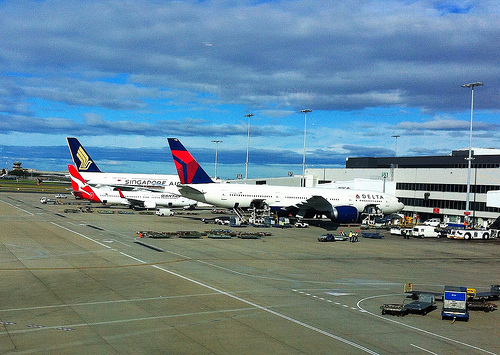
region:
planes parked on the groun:
[45, 112, 437, 265]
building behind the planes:
[291, 114, 496, 214]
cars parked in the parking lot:
[393, 208, 486, 296]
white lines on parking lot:
[118, 224, 271, 346]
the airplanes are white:
[219, 159, 403, 229]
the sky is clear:
[116, 92, 241, 131]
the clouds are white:
[88, 89, 270, 164]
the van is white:
[411, 220, 445, 242]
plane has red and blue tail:
[146, 130, 221, 182]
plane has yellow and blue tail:
[62, 123, 112, 187]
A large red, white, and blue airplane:
[167, 130, 412, 232]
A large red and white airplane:
[65, 170, 200, 215]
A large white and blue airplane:
[60, 130, 225, 187]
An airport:
[316, 147, 497, 224]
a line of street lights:
[190, 75, 476, 206]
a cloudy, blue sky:
[12, 8, 497, 166]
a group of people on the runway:
[342, 226, 362, 246]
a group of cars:
[383, 206, 488, 243]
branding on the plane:
[353, 186, 386, 201]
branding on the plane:
[116, 175, 189, 186]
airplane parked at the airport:
[157, 133, 411, 233]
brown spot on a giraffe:
[62, 163, 194, 212]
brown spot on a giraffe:
[61, 133, 231, 189]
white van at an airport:
[408, 223, 445, 240]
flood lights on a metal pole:
[290, 106, 313, 188]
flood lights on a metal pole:
[457, 77, 482, 221]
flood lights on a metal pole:
[233, 108, 256, 179]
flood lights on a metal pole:
[207, 135, 225, 181]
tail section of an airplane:
[163, 131, 218, 212]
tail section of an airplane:
[62, 131, 112, 188]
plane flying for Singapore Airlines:
[67, 137, 184, 211]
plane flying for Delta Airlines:
[173, 157, 408, 226]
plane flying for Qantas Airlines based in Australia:
[62, 162, 228, 217]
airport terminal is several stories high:
[334, 142, 499, 234]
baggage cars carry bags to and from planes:
[126, 222, 284, 245]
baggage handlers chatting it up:
[312, 225, 366, 246]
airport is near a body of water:
[1, 64, 490, 186]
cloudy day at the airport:
[3, 52, 494, 186]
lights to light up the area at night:
[194, 74, 499, 153]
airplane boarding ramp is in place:
[226, 197, 251, 229]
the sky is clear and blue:
[116, 69, 199, 127]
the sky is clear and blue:
[86, 14, 262, 189]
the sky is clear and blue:
[36, 37, 329, 214]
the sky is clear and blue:
[21, 23, 218, 155]